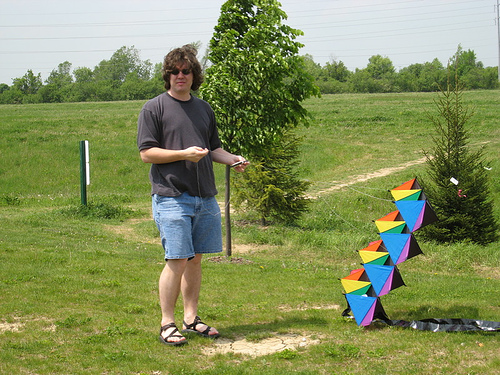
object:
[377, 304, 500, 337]
black tails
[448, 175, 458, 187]
tag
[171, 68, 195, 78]
glasses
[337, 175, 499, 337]
kite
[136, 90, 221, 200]
black shirt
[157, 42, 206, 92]
hair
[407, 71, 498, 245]
tree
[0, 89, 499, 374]
grass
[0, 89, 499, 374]
field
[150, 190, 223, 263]
shorts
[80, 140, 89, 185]
sign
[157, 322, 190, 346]
sandals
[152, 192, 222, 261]
denim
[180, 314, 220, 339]
sandals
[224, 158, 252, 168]
phone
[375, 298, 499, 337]
tail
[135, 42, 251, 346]
he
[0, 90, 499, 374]
ground